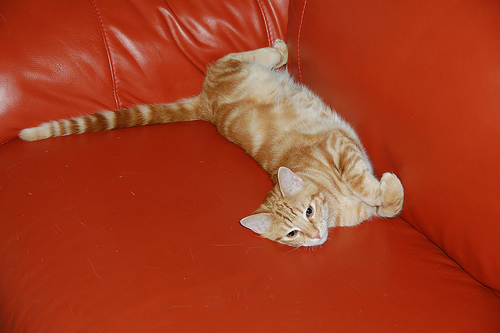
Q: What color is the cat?
A: Orange and white.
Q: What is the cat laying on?
A: A couch.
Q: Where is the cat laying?
A: On the couch.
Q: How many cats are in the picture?
A: One.